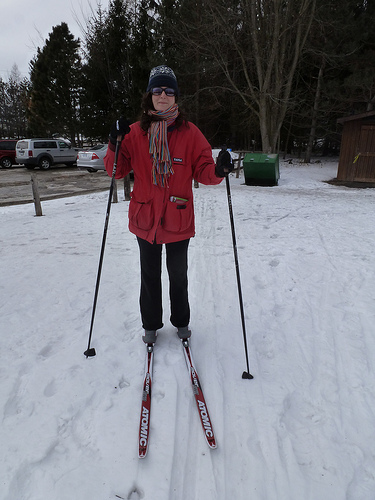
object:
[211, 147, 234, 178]
glove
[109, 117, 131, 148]
hand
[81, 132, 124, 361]
ski pole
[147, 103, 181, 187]
scarf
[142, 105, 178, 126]
persons neck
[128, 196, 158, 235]
pocket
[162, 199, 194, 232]
pocket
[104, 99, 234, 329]
clothing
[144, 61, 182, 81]
design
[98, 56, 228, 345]
person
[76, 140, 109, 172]
silver car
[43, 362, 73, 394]
footprint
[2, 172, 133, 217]
split-log fence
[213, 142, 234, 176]
hand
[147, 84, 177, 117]
face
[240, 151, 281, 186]
green dumpster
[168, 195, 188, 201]
book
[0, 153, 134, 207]
parking lot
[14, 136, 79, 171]
automobiles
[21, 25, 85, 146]
tree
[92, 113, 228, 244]
coat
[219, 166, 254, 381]
poles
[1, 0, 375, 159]
woods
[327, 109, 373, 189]
wooden shed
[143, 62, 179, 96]
hat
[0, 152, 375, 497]
snow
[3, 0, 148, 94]
sky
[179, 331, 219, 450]
ski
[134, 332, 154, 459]
ski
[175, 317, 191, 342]
foot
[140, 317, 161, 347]
foot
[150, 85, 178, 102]
sunglasses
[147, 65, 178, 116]
head